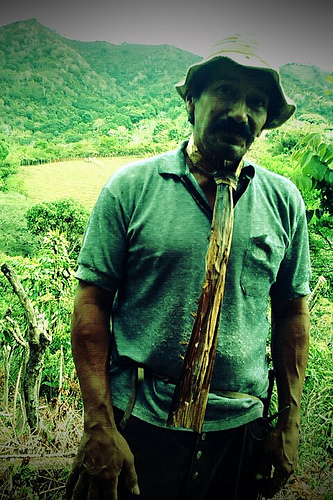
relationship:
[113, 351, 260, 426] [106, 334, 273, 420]
rope around waist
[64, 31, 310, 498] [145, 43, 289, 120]
man wearing hat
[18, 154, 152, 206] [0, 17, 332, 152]
grassy field surrounded by mountains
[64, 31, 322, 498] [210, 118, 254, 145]
man has mustache